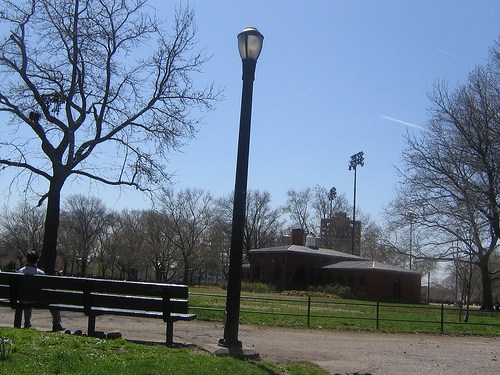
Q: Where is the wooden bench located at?
A: Park.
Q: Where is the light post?
A: On the path.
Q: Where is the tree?
A: By the path.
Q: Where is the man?
A: On the bench.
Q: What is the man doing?
A: Sitting.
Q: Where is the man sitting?
A: On the bench.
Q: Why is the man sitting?
A: TO rest.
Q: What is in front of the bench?
A: A path.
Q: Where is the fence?
A: Across the path.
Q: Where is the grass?
A: On the ground.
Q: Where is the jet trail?
A: In the sky.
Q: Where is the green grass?
A: Behind the bench.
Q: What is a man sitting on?
A: A bench.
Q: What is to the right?
A: A light pole.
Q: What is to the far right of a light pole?
A: A leafless tree.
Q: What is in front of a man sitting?
A: A leafless tree.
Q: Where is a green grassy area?
A: Behind a bench.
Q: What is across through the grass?
A: A brick building.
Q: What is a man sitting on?
A: A long bench.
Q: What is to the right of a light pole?
A: A grey road.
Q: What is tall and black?
A: Light post.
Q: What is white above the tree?
A: Markings in the sky.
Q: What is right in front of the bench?
A: The tree.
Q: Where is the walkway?
A: In front of the bench.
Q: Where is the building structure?
A: On the grass.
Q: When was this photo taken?
A: Daytime.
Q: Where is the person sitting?
A: On bench.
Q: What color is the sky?
A: Blue.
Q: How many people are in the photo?
A: 1.